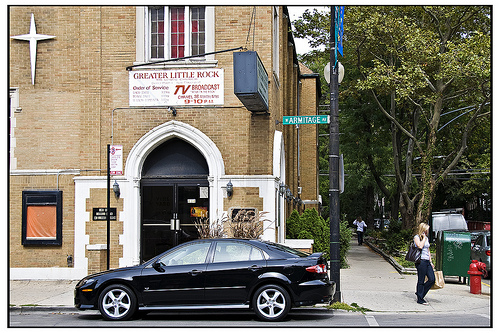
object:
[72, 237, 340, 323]
sedan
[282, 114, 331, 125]
sign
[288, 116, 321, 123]
armitage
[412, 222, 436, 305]
woman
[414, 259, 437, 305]
jeans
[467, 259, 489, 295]
hydrant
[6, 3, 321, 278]
building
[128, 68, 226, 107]
sign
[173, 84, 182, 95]
words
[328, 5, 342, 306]
pole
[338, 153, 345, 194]
sign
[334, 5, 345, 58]
sign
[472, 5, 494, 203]
tree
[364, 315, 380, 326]
stripe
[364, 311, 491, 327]
crosswalk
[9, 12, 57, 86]
cross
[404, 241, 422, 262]
bag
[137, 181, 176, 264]
door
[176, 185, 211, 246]
door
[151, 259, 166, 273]
mirror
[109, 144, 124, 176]
sign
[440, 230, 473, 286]
mailbox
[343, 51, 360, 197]
tree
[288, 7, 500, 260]
background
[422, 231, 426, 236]
phone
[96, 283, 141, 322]
wheel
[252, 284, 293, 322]
wheel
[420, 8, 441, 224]
row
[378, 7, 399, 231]
trees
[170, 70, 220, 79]
little rock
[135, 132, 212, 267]
archway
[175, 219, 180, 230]
pair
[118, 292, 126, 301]
spokes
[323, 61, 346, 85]
light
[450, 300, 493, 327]
corner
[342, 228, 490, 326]
street